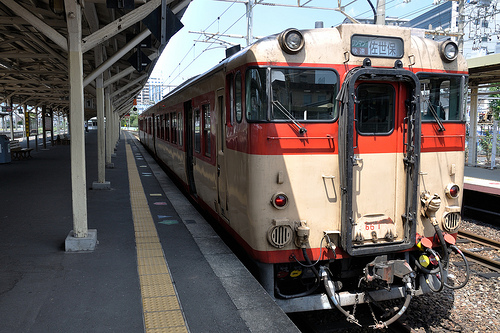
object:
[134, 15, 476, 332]
train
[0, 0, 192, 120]
cover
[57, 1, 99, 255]
supports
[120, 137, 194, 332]
line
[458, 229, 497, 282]
tracks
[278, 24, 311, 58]
lights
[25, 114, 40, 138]
sign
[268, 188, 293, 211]
lights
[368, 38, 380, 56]
letters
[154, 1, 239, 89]
wires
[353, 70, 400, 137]
window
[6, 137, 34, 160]
bench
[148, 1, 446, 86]
sky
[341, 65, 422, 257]
door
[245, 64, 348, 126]
windshield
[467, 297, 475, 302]
rocks